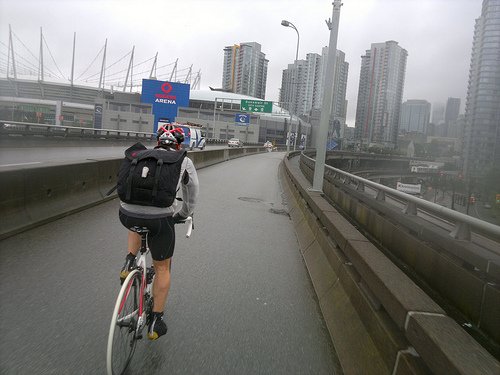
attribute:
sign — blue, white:
[235, 112, 250, 124]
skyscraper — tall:
[450, 0, 499, 192]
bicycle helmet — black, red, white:
[155, 125, 184, 147]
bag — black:
[123, 130, 199, 235]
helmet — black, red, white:
[152, 118, 189, 149]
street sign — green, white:
[237, 96, 282, 120]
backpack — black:
[119, 142, 181, 207]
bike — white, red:
[96, 211, 194, 373]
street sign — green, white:
[239, 98, 272, 111]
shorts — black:
[119, 212, 174, 259]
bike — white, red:
[97, 195, 197, 373]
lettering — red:
[152, 90, 176, 100]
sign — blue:
[141, 79, 189, 129]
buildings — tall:
[214, 33, 410, 156]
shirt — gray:
[118, 142, 188, 213]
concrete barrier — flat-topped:
[285, 172, 428, 361]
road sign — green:
[237, 99, 274, 116]